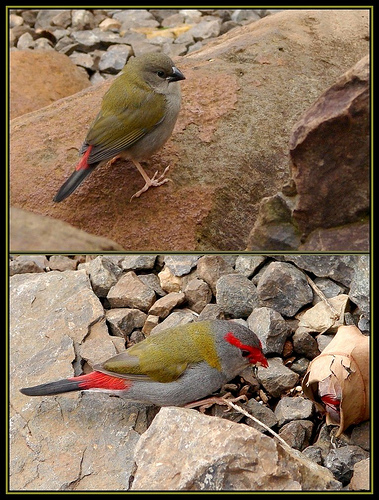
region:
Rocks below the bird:
[7, 257, 369, 491]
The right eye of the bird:
[240, 343, 250, 357]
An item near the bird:
[302, 325, 370, 431]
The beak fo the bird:
[256, 355, 270, 365]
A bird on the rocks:
[21, 319, 267, 408]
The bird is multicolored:
[18, 321, 268, 406]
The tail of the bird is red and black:
[24, 369, 121, 398]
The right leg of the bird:
[123, 157, 170, 199]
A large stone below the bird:
[9, 11, 367, 250]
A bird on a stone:
[51, 55, 183, 203]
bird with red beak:
[252, 347, 270, 372]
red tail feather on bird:
[68, 363, 125, 396]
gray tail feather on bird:
[15, 374, 83, 407]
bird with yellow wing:
[104, 313, 218, 381]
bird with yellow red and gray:
[21, 309, 270, 412]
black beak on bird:
[167, 60, 187, 82]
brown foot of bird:
[122, 154, 175, 207]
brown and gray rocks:
[10, 254, 367, 475]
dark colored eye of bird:
[237, 345, 252, 357]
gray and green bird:
[86, 48, 172, 156]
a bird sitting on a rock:
[33, 43, 200, 199]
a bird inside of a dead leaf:
[289, 317, 370, 435]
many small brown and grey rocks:
[95, 264, 217, 301]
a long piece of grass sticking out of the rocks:
[227, 396, 299, 449]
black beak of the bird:
[164, 64, 189, 82]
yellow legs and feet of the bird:
[105, 152, 172, 205]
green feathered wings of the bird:
[92, 74, 161, 134]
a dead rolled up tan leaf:
[327, 335, 369, 409]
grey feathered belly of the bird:
[155, 379, 221, 406]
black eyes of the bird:
[235, 339, 264, 359]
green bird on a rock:
[43, 48, 205, 206]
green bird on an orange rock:
[0, 4, 207, 250]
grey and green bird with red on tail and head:
[18, 316, 271, 409]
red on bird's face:
[219, 314, 269, 384]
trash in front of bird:
[302, 323, 368, 433]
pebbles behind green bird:
[11, 7, 275, 205]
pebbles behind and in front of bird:
[9, 255, 377, 485]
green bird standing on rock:
[42, 22, 219, 220]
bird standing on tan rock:
[0, 272, 307, 488]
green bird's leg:
[124, 158, 185, 205]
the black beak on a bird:
[170, 66, 185, 82]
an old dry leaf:
[301, 325, 369, 433]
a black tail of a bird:
[19, 378, 79, 397]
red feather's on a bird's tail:
[73, 368, 125, 392]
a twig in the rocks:
[305, 275, 337, 318]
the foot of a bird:
[126, 163, 173, 197]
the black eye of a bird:
[238, 348, 250, 360]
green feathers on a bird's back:
[102, 318, 212, 380]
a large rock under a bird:
[8, 9, 367, 249]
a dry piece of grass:
[223, 397, 290, 448]